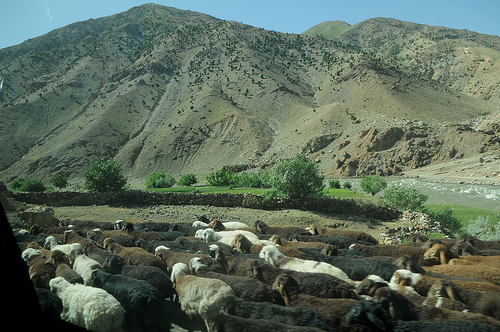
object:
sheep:
[90, 269, 167, 331]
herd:
[21, 217, 499, 330]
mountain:
[2, 1, 499, 192]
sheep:
[169, 262, 235, 332]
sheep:
[47, 277, 128, 331]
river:
[322, 177, 500, 213]